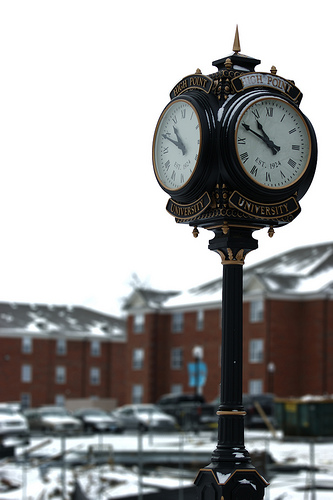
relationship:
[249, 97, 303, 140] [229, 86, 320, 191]
numerals on clock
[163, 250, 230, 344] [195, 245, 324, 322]
snow on roof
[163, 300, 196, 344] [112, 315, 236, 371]
window on building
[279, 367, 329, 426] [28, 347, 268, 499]
dumpster in lot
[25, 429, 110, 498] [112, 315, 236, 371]
tree behind building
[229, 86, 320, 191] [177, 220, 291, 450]
clock on pole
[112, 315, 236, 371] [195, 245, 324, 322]
building has roof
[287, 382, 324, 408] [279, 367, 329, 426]
lid on dumpster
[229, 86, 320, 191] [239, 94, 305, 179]
clock has faces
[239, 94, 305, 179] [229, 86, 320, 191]
faces of clock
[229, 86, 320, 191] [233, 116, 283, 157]
clock has hand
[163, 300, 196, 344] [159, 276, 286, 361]
window of third floor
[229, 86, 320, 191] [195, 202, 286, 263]
clock has bottom